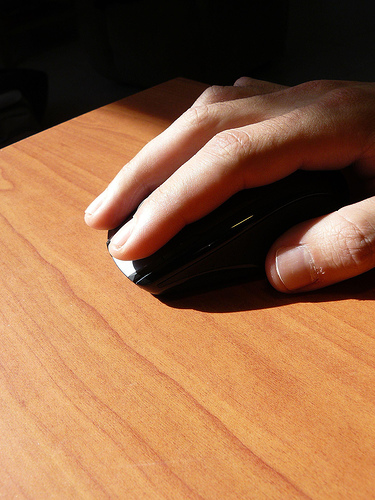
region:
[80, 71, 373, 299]
The hand is holding a mouse.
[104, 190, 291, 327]
The mouse is on a table.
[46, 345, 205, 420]
The table is made out of wood.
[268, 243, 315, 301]
The finger nails have been clipped.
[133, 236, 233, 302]
The mouse is black.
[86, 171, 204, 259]
The fingers are white.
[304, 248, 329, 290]
The cuticle has not been cut.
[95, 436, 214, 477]
The table has a scratch.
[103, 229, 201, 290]
The mouse is silver and black.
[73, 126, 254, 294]
Two fingers are on the clickers.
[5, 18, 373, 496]
A hand holding a computer mouse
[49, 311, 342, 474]
A brown wooden table surface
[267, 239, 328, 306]
A man's thumb nail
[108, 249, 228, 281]
A mouse button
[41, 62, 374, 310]
A computer mouse under a hand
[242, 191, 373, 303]
A man's thumb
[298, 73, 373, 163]
A man's knuckles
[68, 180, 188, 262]
A man's two fingers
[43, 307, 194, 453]
Wood grain patterns on a table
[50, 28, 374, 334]
A man's hand controlling a computer mouse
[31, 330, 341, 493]
a wooden table in the picture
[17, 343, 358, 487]
this wood is colored light brown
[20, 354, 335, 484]
a light brown colored piece of wood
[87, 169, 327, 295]
a mouse in the picture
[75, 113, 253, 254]
two fingers on a mouse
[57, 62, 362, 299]
a person's hand is controlling the mouse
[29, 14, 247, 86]
a black background in the picture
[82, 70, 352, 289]
this person has five fingers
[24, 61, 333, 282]
light on a person's hand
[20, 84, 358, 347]
the mouse is on the table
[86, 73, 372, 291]
right hand on a computer mouse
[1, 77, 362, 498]
brown wood desktop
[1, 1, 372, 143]
dark room behind the desk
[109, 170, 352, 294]
black and gray mouse on desk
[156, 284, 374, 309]
shadow of mouse on desk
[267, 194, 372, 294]
thumb on side of mouse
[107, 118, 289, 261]
index finger on mouse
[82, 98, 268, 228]
middle finger on mouse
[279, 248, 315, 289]
the finger nail on the thumb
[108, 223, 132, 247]
the finger nail on the index finger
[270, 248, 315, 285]
finger nail on the thumb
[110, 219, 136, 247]
finger nail on the finger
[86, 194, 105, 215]
finger nail on the finger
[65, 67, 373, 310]
hand resting on table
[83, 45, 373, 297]
hand resting on cell phone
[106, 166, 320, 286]
cell phone on table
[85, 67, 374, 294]
hand on the table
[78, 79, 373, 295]
fingers on the hand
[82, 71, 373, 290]
fingers attached to hand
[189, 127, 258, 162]
knuckle on the finger